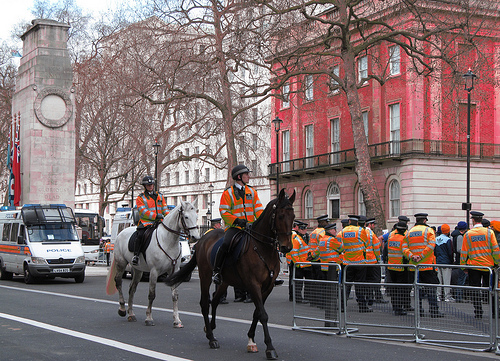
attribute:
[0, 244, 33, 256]
stripe — orange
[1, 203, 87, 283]
police van — white, orange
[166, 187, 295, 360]
horse — brown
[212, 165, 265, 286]
policeman — sitting, riding, male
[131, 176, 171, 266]
policeman — riding, male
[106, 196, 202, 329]
horse — white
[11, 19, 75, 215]
clocktower — stone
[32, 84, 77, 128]
place-for-clock — empty, round, circular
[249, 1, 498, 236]
tree — bare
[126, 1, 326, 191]
tree — bare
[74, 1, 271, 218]
tree — bare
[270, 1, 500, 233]
building — red, behind, brick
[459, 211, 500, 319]
cops — grouped, standing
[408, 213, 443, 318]
cops — grouped, standing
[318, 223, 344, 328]
cops — grouped, standing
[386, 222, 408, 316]
cops — grouped, standing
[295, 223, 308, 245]
cops — grouped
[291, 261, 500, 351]
barricade — metal, controlling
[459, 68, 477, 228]
streetlight — black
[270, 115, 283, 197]
streetlight — black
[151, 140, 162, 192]
streetlight — black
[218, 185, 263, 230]
vest — orange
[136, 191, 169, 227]
vest — orange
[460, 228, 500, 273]
vest — orange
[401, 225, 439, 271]
vest — orange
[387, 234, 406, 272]
vest — orange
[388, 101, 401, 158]
window — rectangular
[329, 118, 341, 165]
window — rectangular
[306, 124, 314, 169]
window — rectangular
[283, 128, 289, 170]
window — rectangular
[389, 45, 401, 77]
window — rectangular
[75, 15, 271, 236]
building — behind